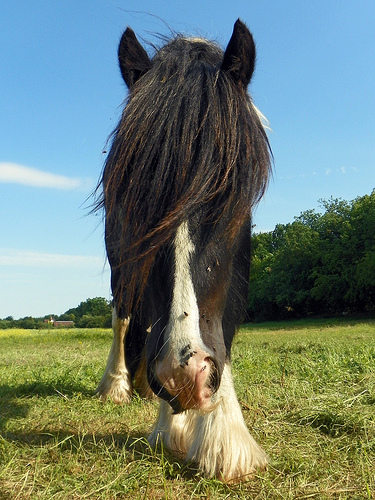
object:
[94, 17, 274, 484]
horse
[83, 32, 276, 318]
mane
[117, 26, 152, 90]
ear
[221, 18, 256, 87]
ear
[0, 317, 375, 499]
field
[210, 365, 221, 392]
nostril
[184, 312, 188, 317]
fly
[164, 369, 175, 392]
nostril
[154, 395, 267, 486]
hoof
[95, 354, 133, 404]
hoof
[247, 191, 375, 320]
trees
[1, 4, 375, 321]
sky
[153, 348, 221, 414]
nose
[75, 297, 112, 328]
trees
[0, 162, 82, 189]
cloud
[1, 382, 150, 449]
shadow